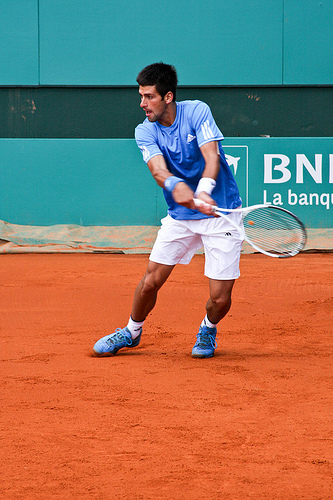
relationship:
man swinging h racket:
[91, 63, 244, 358] [192, 198, 306, 258]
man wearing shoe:
[91, 63, 244, 358] [89, 325, 142, 356]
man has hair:
[91, 63, 244, 358] [135, 56, 182, 107]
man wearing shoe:
[91, 63, 244, 358] [189, 323, 218, 356]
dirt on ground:
[0, 252, 331, 498] [0, 223, 332, 498]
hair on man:
[135, 62, 177, 102] [91, 61, 244, 358]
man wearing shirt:
[91, 63, 244, 358] [134, 93, 245, 223]